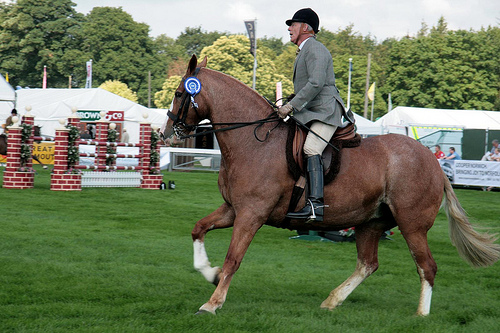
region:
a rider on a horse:
[155, 0, 499, 327]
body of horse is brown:
[140, 50, 486, 329]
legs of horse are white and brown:
[181, 210, 445, 325]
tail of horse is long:
[432, 157, 497, 275]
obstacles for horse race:
[3, 103, 178, 203]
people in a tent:
[392, 97, 499, 192]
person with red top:
[431, 138, 448, 161]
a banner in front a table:
[451, 152, 499, 189]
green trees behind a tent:
[367, 19, 499, 195]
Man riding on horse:
[272, 8, 350, 220]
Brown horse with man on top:
[159, 52, 493, 317]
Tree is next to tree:
[55, 7, 156, 109]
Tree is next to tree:
[0, 2, 85, 87]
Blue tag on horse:
[180, 77, 201, 97]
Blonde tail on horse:
[439, 164, 497, 275]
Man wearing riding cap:
[276, 7, 353, 225]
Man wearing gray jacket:
[273, 8, 355, 225]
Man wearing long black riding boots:
[278, 11, 352, 223]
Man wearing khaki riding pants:
[283, 8, 350, 223]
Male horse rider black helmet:
[283, 5, 318, 31]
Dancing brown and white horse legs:
[181, 211, 261, 318]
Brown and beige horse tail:
[435, 176, 495, 271]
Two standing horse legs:
[310, 230, 445, 320]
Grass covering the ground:
[6, 201, 146, 301]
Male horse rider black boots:
[281, 152, 334, 223]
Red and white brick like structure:
[41, 129, 86, 193]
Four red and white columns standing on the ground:
[2, 122, 163, 194]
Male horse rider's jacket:
[281, 39, 355, 129]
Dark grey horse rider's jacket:
[285, 36, 355, 127]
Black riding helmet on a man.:
[283, 7, 318, 29]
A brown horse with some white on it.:
[158, 52, 498, 318]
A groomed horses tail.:
[440, 169, 499, 264]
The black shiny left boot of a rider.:
[286, 152, 325, 220]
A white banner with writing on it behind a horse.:
[453, 159, 499, 187]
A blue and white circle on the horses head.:
[183, 77, 200, 96]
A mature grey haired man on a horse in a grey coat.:
[279, 8, 345, 218]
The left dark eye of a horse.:
[172, 90, 184, 98]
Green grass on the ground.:
[7, 173, 499, 331]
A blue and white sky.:
[81, 3, 499, 39]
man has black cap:
[277, 1, 332, 34]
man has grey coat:
[290, 37, 338, 112]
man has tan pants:
[292, 109, 337, 156]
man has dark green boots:
[297, 153, 332, 206]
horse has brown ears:
[170, 56, 217, 65]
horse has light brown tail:
[440, 182, 492, 274]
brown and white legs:
[148, 197, 461, 329]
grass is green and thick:
[13, 224, 120, 290]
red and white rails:
[70, 131, 145, 169]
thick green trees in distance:
[17, 6, 487, 105]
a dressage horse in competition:
[159, 53, 495, 323]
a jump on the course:
[49, 120, 161, 193]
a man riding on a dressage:
[272, 4, 349, 241]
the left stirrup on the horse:
[282, 195, 326, 226]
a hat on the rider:
[286, 7, 319, 43]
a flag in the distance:
[364, 76, 377, 120]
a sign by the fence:
[452, 160, 498, 190]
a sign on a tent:
[71, 108, 124, 119]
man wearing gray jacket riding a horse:
[273, 6, 348, 226]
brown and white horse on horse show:
[158, 59, 492, 317]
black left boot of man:
[286, 149, 328, 223]